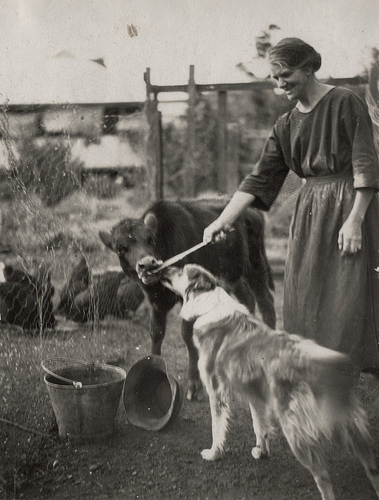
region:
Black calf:
[102, 195, 276, 396]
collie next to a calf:
[159, 264, 376, 498]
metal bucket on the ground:
[40, 357, 122, 440]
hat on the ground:
[122, 352, 182, 432]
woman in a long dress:
[205, 41, 376, 366]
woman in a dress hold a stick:
[150, 37, 377, 368]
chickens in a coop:
[5, 259, 139, 320]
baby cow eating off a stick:
[102, 200, 275, 407]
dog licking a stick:
[161, 268, 374, 489]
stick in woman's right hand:
[146, 218, 235, 271]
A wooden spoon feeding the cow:
[145, 220, 237, 283]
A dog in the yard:
[160, 263, 375, 497]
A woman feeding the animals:
[111, 31, 373, 490]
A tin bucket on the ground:
[24, 347, 133, 450]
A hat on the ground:
[121, 353, 184, 432]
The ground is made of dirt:
[62, 459, 256, 497]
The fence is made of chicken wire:
[7, 130, 104, 348]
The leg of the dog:
[198, 400, 242, 467]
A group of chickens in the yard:
[2, 250, 143, 337]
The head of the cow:
[94, 209, 170, 289]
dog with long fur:
[165, 266, 377, 497]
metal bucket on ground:
[41, 358, 126, 438]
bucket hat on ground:
[125, 354, 181, 431]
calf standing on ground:
[102, 198, 273, 402]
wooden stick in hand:
[145, 225, 233, 274]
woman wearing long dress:
[206, 38, 377, 373]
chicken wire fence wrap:
[2, 98, 153, 462]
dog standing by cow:
[162, 263, 373, 498]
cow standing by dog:
[96, 199, 276, 390]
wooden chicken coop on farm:
[144, 70, 376, 277]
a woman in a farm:
[5, 0, 374, 499]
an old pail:
[31, 348, 130, 449]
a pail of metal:
[36, 342, 128, 447]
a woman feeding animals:
[123, 28, 377, 395]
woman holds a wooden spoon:
[135, 28, 377, 311]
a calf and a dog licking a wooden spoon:
[96, 184, 371, 495]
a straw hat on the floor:
[113, 345, 189, 442]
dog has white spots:
[156, 260, 376, 498]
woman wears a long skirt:
[219, 21, 377, 385]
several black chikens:
[0, 246, 157, 339]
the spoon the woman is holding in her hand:
[141, 228, 227, 280]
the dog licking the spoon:
[149, 259, 372, 499]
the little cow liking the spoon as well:
[95, 192, 282, 356]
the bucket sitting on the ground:
[37, 356, 128, 439]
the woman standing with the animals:
[205, 41, 375, 379]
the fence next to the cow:
[4, 104, 151, 411]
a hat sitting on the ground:
[119, 355, 182, 431]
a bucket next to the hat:
[36, 353, 123, 440]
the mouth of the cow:
[134, 254, 162, 285]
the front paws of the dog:
[192, 439, 263, 461]